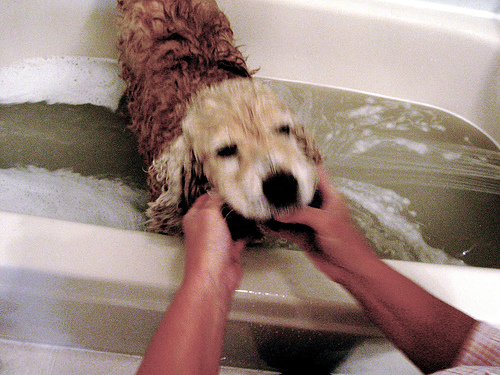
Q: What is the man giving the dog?
A: A bath.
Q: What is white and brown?
A: Dog.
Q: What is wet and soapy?
A: Water.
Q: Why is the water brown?
A: Dirty.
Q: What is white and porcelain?
A: Tub.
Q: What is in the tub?
A: Dirty soapy water.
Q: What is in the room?
A: White bathtub.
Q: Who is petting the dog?
A: A man.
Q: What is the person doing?
A: Giving the dog a bath.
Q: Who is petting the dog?
A: A man.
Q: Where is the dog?
A: In the bath tub.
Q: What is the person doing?
A: Bathing the dog.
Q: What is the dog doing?
A: Standing in the bath tub.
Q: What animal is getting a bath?
A: The dog.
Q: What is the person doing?
A: Giving the dog a bath.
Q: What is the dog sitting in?
A: A bathtub.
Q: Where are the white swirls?
A: In the bath water.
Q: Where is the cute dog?
A: In the bath tub.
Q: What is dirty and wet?
A: The bath water.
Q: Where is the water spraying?
A: In the tub.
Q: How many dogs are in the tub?
A: 1.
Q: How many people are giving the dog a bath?
A: 1.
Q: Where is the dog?
A: In the tub.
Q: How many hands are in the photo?
A: 2.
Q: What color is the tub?
A: White.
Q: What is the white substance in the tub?
A: Soap.